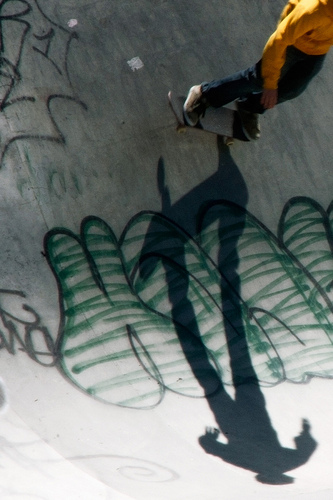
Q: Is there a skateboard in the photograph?
A: Yes, there is a skateboard.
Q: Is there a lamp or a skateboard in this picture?
A: Yes, there is a skateboard.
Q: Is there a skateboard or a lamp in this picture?
A: Yes, there is a skateboard.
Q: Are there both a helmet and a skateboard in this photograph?
A: No, there is a skateboard but no helmets.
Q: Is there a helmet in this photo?
A: No, there are no helmets.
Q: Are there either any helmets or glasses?
A: No, there are no helmets or glasses.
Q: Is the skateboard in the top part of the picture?
A: Yes, the skateboard is in the top of the image.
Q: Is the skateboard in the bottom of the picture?
A: No, the skateboard is in the top of the image.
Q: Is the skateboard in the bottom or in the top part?
A: The skateboard is in the top of the image.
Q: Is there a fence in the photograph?
A: No, there are no fences.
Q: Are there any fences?
A: No, there are no fences.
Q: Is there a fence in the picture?
A: No, there are no fences.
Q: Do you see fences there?
A: No, there are no fences.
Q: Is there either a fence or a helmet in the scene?
A: No, there are no fences or helmets.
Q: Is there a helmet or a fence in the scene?
A: No, there are no fences or helmets.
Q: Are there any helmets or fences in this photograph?
A: No, there are no fences or helmets.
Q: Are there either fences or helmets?
A: No, there are no fences or helmets.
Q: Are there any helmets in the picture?
A: No, there are no helmets.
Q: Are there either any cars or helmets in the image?
A: No, there are no helmets or cars.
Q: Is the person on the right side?
A: Yes, the person is on the right of the image.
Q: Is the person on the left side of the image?
A: No, the person is on the right of the image.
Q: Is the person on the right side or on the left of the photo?
A: The person is on the right of the image.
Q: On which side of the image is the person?
A: The person is on the right of the image.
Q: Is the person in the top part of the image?
A: Yes, the person is in the top of the image.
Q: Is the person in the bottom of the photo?
A: No, the person is in the top of the image.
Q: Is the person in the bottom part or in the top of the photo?
A: The person is in the top of the image.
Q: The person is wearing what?
A: The person is wearing trousers.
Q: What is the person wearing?
A: The person is wearing trousers.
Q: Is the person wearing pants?
A: Yes, the person is wearing pants.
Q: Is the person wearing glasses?
A: No, the person is wearing pants.